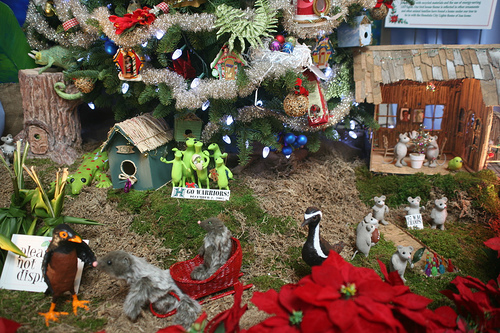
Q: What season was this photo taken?
A: Christmas season.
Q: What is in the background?
A: A Christmas tree.